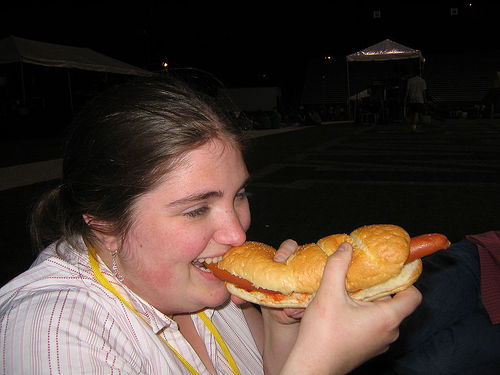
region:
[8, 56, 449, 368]
woman eating a hotdog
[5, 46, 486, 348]
woman eating a hotdog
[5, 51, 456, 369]
woman eating a hotdog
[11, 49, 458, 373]
woman eating a hotdog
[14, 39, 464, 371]
woman eating a hotdog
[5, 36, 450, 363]
woman eating a hotdog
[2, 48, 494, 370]
woman eating a hotdog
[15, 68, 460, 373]
woman eating a hotdog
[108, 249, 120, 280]
earring of the woman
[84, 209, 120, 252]
ear of the woman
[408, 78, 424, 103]
man wearing tees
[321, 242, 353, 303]
thumb finger of the woman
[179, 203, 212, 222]
eye of the woman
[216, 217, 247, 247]
nose of the woman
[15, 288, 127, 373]
woman wearing white shirts with stripes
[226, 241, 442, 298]
woman holding hotdog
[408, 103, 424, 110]
man wearing black shorts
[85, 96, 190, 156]
woman with brown color hair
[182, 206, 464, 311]
THE HOT DOG IS A FOOT LONG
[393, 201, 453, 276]
THE HOT DOG IS LONGER THAN THE BUN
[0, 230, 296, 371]
THE GIRL IS WEARING A PINK STRIPED SHIRT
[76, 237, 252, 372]
THE GIRL IS WEARING A SKINNY YELLOW LANYARD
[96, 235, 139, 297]
THE GIRL IS WEARING EARRINGS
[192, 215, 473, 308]
THE HOT DOG HAS KETSUP ON IT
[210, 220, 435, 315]
THE HOT DOG IS IN A BIG BUN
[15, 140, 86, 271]
THE GIRL IS WEARING A PONY TAIL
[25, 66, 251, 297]
THE GIRL'S HAIR IS BROWN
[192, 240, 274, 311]
THE GIRL IS BITING THE LONG HOT DOG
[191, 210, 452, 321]
THE HOTDOG IS LONG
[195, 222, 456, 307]
THE HOTDOG IS IN A BUN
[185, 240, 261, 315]
THE GIRL IS BITING THE HOTDOG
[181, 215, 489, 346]
THE GIRL IS HOLDING A HOT DOG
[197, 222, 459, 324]
THE GIRL IS EATING A HOTDOG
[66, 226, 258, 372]
THE GIRL IS WEARING A YELLOW LANYARD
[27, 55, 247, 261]
THE GIRL HAS A PONY TAIL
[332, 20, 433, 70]
THE TENT IS WHITE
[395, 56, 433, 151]
THE MAN IS WALKING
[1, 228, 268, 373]
THE GIRLS SHIRT HAS PINK STRIPES